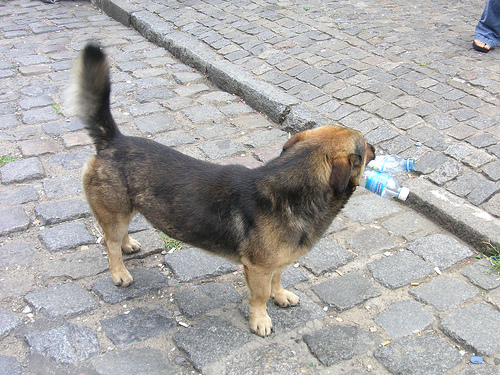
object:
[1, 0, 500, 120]
road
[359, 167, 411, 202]
bottle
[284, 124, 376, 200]
head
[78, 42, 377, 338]
dog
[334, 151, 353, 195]
ear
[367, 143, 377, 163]
nose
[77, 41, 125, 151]
tail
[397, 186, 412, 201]
bottle cap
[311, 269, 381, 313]
brick